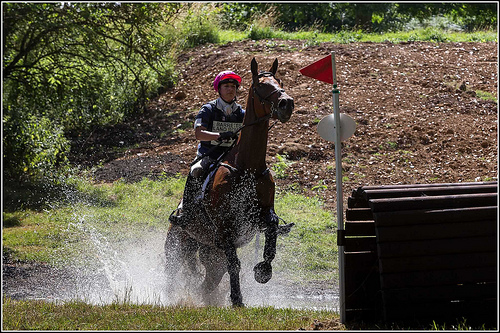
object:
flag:
[300, 55, 334, 83]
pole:
[332, 51, 345, 326]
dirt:
[364, 57, 466, 138]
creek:
[0, 271, 341, 310]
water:
[0, 276, 342, 305]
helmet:
[214, 71, 242, 91]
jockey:
[183, 70, 247, 233]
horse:
[165, 57, 295, 309]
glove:
[220, 131, 233, 138]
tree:
[0, 1, 158, 105]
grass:
[2, 298, 341, 329]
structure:
[346, 183, 500, 333]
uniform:
[195, 99, 245, 158]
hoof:
[253, 262, 272, 284]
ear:
[251, 57, 258, 76]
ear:
[269, 58, 278, 74]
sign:
[317, 113, 356, 142]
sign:
[211, 121, 243, 147]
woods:
[4, 4, 172, 217]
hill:
[97, 39, 482, 182]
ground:
[0, 37, 500, 333]